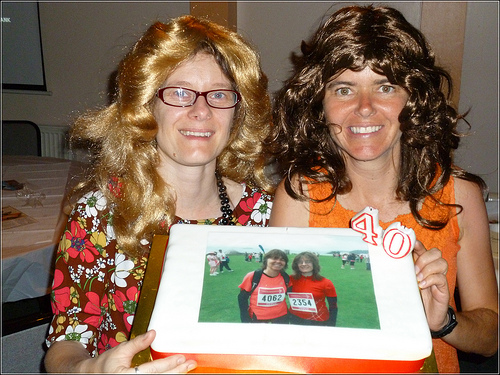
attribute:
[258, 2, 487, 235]
wig — brown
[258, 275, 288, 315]
shirt — red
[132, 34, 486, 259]
women — chests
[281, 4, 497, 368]
woman — smiling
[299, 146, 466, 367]
dress — orange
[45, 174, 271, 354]
shirt — beige 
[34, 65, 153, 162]
chair — gray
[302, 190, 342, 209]
orange shirt — orange 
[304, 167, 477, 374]
shirt — orange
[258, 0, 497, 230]
hair — brown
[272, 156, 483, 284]
shirt — orange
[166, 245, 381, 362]
grass — green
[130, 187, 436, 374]
cake — corner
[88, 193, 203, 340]
dress — flowery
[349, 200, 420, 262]
number — 40, white, red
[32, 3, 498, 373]
women — smiling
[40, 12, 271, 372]
woman — smiling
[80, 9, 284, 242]
wig — blonde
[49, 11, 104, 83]
wall — in background